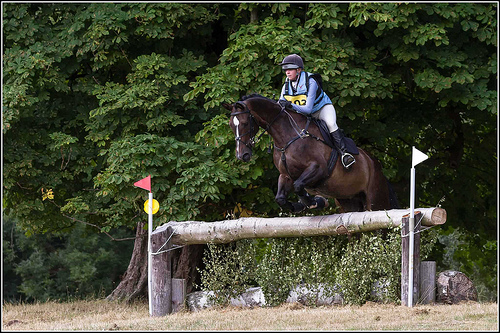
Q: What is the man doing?
A: Riding a horse.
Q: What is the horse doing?
A: Jumping.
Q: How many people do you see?
A: 1.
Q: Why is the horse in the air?
A: Jumping.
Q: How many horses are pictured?
A: 1.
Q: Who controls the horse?
A: The rider.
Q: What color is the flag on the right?
A: White.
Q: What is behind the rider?
A: Trees.